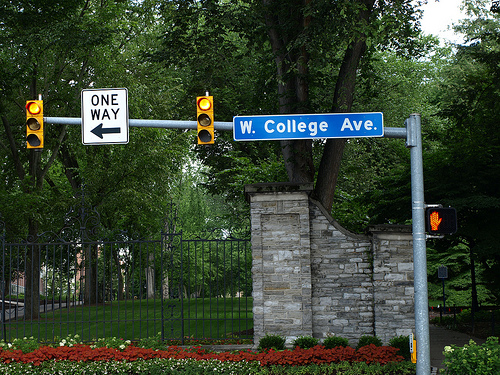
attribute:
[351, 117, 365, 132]
letter — white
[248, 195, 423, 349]
wall — brick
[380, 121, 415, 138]
pole — Gray 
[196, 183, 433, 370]
wall — brick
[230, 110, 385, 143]
sign — blue, white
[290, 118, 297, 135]
letter — White 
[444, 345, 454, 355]
flower — white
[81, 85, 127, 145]
sign — white, black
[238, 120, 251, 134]
letter — white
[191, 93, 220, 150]
light — orange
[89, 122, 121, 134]
arrow — black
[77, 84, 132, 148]
sign — black, white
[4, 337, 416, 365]
flowers — red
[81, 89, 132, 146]
sign — blue, white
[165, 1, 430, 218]
tree — leafy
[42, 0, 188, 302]
tree — leafy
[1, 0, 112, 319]
tree — leafy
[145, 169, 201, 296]
tree — leafy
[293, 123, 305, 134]
letter — white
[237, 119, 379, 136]
lettering — white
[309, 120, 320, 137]
letter — white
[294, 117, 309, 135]
letter — white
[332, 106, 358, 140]
letter — White 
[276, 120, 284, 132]
letter — white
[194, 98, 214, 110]
light — orange